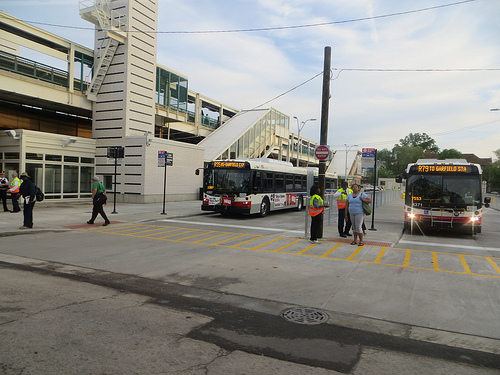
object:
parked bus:
[402, 158, 490, 236]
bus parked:
[195, 158, 338, 217]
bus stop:
[192, 141, 500, 258]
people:
[310, 182, 372, 247]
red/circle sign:
[315, 146, 329, 160]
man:
[19, 174, 37, 230]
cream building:
[0, 0, 360, 204]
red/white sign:
[314, 145, 329, 160]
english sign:
[317, 148, 327, 158]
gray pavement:
[6, 268, 155, 358]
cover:
[282, 307, 329, 325]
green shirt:
[92, 182, 105, 194]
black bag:
[94, 193, 108, 207]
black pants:
[89, 198, 109, 222]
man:
[86, 176, 110, 227]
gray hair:
[93, 176, 100, 180]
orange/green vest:
[309, 194, 325, 216]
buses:
[194, 158, 491, 233]